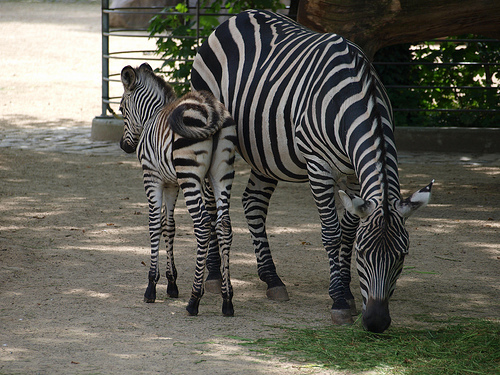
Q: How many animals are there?
A: 2.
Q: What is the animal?
A: Zebra.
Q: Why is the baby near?
A: Mama.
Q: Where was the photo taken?
A: Zoo.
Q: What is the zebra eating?
A: Grass.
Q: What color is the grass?
A: Green.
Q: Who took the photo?
A: Zookeeper.